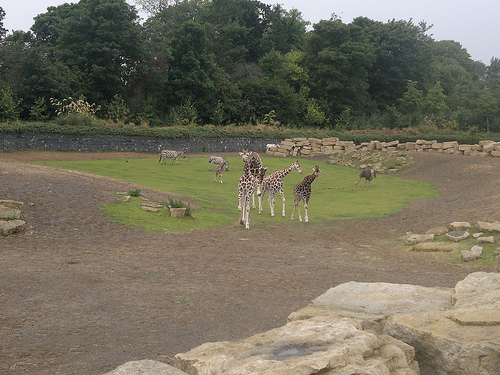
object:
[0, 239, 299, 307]
ground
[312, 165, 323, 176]
head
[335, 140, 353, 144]
boulders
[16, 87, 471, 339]
park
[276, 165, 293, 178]
neck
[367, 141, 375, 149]
stone blocks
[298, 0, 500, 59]
sky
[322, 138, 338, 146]
stone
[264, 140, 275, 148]
stone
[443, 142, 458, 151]
stone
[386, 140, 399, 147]
stone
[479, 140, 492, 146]
stone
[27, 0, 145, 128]
tree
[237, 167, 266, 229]
giraffe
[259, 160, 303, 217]
giraffe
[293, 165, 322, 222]
giraffe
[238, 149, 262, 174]
giraffe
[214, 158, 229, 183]
giraffe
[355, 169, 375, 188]
gazelle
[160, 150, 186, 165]
zebra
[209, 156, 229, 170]
zebra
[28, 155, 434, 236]
grass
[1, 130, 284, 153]
wall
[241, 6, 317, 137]
trees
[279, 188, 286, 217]
leg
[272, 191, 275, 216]
leg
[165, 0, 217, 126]
tree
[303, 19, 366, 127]
tree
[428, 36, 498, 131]
tree